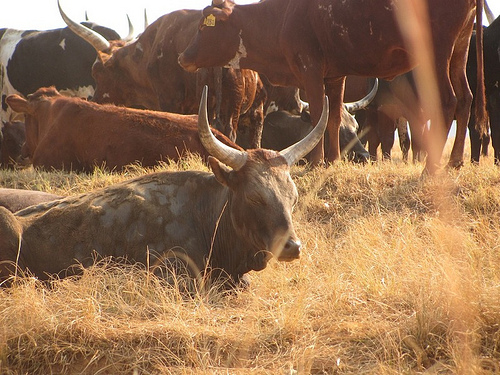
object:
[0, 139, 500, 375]
grass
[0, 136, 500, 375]
plain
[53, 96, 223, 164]
body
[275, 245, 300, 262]
mouth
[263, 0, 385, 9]
back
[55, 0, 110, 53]
horn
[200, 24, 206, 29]
eye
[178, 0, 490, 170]
cow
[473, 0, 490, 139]
tail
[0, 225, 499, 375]
ground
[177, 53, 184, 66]
nose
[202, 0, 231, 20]
ear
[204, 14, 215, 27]
tag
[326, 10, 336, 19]
spots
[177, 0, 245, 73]
head